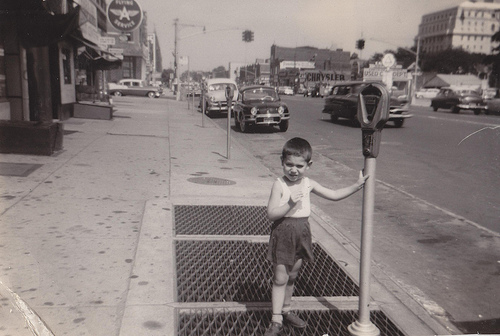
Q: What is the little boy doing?
A: Standing next to a parking meter.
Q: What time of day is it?
A: Day time.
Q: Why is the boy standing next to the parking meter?
A: He is looking up the street.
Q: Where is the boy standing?
A: By the parking meter.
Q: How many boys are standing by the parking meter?
A: One.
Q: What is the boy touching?
A: The parking meter.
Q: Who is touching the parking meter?
A: A boy.